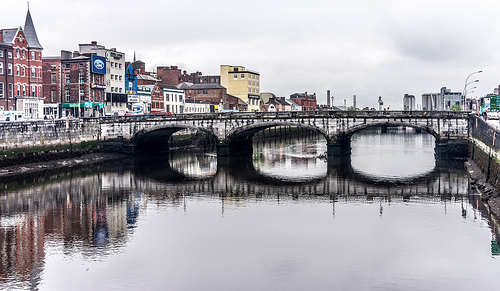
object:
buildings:
[0, 1, 500, 121]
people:
[383, 105, 390, 115]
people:
[315, 104, 323, 114]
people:
[230, 108, 233, 115]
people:
[44, 111, 130, 120]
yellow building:
[220, 65, 262, 118]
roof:
[23, 1, 43, 49]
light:
[463, 70, 482, 110]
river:
[0, 127, 500, 291]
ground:
[414, 176, 426, 182]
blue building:
[125, 61, 138, 110]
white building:
[78, 41, 129, 116]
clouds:
[0, 0, 500, 111]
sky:
[0, 0, 498, 111]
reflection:
[0, 140, 500, 290]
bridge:
[79, 110, 474, 175]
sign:
[91, 54, 106, 74]